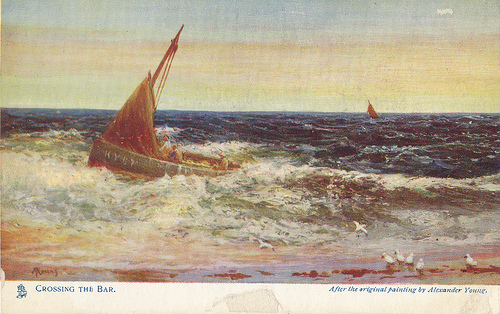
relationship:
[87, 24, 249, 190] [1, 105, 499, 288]
boat on water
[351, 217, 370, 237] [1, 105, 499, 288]
bird on water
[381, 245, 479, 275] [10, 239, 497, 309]
birds on beach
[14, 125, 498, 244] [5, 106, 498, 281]
waves in ocean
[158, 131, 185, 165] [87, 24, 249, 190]
people in boat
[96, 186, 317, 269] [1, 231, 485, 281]
water washing up on shore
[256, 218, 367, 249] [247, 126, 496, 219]
birds flying over water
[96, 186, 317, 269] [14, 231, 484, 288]
water washing up on shore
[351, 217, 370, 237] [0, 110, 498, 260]
bird flying water